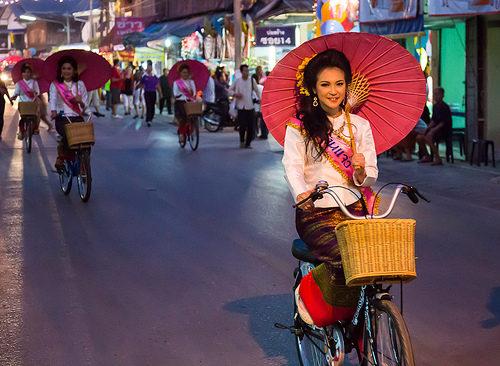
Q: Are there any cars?
A: No, there are no cars.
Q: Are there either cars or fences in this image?
A: No, there are no cars or fences.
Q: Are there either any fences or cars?
A: No, there are no cars or fences.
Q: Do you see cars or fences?
A: No, there are no cars or fences.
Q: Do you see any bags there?
A: No, there are no bags.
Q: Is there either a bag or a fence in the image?
A: No, there are no bags or fences.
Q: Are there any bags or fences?
A: No, there are no bags or fences.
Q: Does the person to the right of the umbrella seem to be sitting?
A: Yes, the person is sitting.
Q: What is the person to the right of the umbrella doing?
A: The person is sitting.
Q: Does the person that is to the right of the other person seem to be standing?
A: No, the person is sitting.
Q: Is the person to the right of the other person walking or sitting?
A: The person is sitting.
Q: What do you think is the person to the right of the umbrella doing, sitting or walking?
A: The person is sitting.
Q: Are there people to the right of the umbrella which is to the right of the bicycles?
A: Yes, there is a person to the right of the umbrella.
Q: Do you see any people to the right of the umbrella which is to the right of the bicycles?
A: Yes, there is a person to the right of the umbrella.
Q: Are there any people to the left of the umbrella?
A: No, the person is to the right of the umbrella.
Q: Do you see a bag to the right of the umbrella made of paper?
A: No, there is a person to the right of the umbrella.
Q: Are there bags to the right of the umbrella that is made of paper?
A: No, there is a person to the right of the umbrella.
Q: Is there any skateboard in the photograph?
A: No, there are no skateboards.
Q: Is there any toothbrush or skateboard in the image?
A: No, there are no skateboards or toothbrushes.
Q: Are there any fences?
A: No, there are no fences.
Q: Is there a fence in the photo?
A: No, there are no fences.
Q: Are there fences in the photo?
A: No, there are no fences.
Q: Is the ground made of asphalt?
A: Yes, the ground is made of asphalt.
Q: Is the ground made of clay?
A: No, the ground is made of asphalt.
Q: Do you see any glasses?
A: No, there are no glasses.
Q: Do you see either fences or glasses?
A: No, there are no glasses or fences.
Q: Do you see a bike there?
A: Yes, there is a bike.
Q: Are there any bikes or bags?
A: Yes, there is a bike.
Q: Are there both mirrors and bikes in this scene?
A: No, there is a bike but no mirrors.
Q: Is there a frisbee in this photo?
A: No, there are no frisbees.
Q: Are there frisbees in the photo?
A: No, there are no frisbees.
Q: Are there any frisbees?
A: No, there are no frisbees.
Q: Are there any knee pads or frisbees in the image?
A: No, there are no frisbees or knee pads.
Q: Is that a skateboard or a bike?
A: That is a bike.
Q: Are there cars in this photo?
A: No, there are no cars.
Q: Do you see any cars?
A: No, there are no cars.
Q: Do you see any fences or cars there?
A: No, there are no cars or fences.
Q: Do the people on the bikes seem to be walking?
A: Yes, the people are walking.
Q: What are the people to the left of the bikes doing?
A: The people are walking.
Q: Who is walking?
A: The people are walking.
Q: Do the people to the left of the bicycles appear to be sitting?
A: No, the people are walking.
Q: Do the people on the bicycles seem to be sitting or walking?
A: The people are walking.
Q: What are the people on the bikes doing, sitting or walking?
A: The people are walking.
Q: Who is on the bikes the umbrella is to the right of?
A: The people are on the bicycles.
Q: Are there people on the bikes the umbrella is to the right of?
A: Yes, there are people on the bikes.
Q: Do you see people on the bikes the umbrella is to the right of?
A: Yes, there are people on the bikes.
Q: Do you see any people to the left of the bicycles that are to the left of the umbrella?
A: Yes, there are people to the left of the bikes.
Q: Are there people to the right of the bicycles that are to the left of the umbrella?
A: No, the people are to the left of the bicycles.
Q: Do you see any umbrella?
A: Yes, there is an umbrella.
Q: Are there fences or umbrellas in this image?
A: Yes, there is an umbrella.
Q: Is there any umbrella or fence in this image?
A: Yes, there is an umbrella.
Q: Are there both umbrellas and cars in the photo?
A: No, there is an umbrella but no cars.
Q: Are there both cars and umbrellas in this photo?
A: No, there is an umbrella but no cars.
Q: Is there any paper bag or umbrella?
A: Yes, there is a paper umbrella.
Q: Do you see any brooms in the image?
A: No, there are no brooms.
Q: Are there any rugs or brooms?
A: No, there are no brooms or rugs.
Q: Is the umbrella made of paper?
A: Yes, the umbrella is made of paper.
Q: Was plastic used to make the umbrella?
A: No, the umbrella is made of paper.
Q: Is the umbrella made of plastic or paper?
A: The umbrella is made of paper.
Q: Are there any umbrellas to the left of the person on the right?
A: Yes, there is an umbrella to the left of the person.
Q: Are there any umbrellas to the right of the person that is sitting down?
A: No, the umbrella is to the left of the person.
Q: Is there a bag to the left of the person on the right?
A: No, there is an umbrella to the left of the person.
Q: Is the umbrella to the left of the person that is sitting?
A: Yes, the umbrella is to the left of the person.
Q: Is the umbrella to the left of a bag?
A: No, the umbrella is to the left of the person.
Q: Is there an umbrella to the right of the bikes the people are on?
A: Yes, there is an umbrella to the right of the bikes.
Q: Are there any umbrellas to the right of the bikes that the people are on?
A: Yes, there is an umbrella to the right of the bikes.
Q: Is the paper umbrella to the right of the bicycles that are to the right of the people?
A: Yes, the umbrella is to the right of the bicycles.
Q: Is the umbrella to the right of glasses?
A: No, the umbrella is to the right of the bicycles.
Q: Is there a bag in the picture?
A: No, there are no bags.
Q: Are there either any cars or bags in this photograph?
A: No, there are no bags or cars.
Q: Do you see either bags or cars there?
A: No, there are no bags or cars.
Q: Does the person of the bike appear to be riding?
A: Yes, the person is riding.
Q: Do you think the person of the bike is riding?
A: Yes, the person is riding.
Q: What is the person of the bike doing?
A: The person is riding.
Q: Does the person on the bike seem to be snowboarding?
A: No, the person is riding.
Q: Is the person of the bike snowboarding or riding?
A: The person is riding.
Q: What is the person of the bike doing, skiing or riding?
A: The person is riding.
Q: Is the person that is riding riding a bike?
A: Yes, the person is riding a bike.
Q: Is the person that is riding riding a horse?
A: No, the person is riding a bike.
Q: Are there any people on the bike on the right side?
A: Yes, there is a person on the bike.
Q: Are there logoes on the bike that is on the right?
A: No, there is a person on the bike.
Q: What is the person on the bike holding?
A: The person is holding the umbrella.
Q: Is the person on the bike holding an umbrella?
A: Yes, the person is holding an umbrella.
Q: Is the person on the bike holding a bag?
A: No, the person is holding an umbrella.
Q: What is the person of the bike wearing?
A: The person is wearing earrings.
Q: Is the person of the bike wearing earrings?
A: Yes, the person is wearing earrings.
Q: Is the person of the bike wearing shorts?
A: No, the person is wearing earrings.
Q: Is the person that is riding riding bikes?
A: Yes, the person is riding bikes.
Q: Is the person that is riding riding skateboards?
A: No, the person is riding bikes.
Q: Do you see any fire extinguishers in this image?
A: No, there are no fire extinguishers.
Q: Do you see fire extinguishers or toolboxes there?
A: No, there are no fire extinguishers or toolboxes.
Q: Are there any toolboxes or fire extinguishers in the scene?
A: No, there are no fire extinguishers or toolboxes.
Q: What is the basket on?
A: The basket is on the bike.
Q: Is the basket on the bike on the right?
A: Yes, the basket is on the bike.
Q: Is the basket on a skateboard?
A: No, the basket is on the bike.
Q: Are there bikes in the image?
A: Yes, there are bikes.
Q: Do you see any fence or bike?
A: Yes, there are bikes.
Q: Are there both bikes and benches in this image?
A: No, there are bikes but no benches.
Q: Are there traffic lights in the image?
A: No, there are no traffic lights.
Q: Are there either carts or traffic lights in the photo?
A: No, there are no traffic lights or carts.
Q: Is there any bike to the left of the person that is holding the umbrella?
A: Yes, there are bikes to the left of the person.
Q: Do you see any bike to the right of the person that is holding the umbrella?
A: No, the bikes are to the left of the person.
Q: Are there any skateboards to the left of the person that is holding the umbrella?
A: No, there are bikes to the left of the person.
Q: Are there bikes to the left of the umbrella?
A: Yes, there are bikes to the left of the umbrella.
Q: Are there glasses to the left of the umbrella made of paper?
A: No, there are bikes to the left of the umbrella.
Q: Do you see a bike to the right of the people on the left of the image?
A: Yes, there are bikes to the right of the people.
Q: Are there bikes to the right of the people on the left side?
A: Yes, there are bikes to the right of the people.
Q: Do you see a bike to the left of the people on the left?
A: No, the bikes are to the right of the people.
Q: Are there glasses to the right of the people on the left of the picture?
A: No, there are bikes to the right of the people.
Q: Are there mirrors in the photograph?
A: No, there are no mirrors.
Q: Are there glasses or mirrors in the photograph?
A: No, there are no mirrors or glasses.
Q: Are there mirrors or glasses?
A: No, there are no mirrors or glasses.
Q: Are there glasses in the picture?
A: No, there are no glasses.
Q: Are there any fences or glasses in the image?
A: No, there are no glasses or fences.